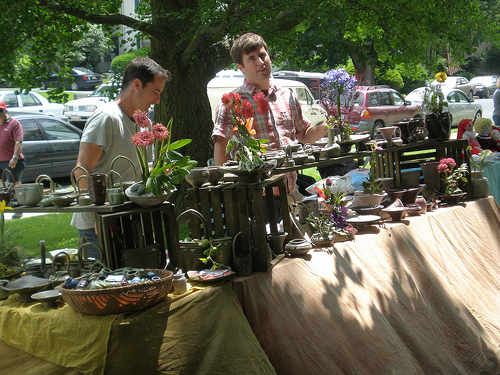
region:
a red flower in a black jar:
[419, 68, 459, 138]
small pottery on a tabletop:
[280, 176, 406, 251]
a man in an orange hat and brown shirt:
[1, 101, 26, 191]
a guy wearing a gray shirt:
[72, 51, 174, 188]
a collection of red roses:
[220, 88, 275, 164]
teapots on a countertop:
[8, 171, 95, 210]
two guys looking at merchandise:
[70, 36, 336, 244]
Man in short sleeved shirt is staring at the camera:
[203, 30, 336, 157]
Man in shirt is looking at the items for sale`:
[63, 50, 183, 253]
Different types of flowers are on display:
[115, 60, 415, 196]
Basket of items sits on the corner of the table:
[50, 257, 187, 320]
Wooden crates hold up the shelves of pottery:
[77, 141, 497, 298]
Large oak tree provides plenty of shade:
[18, 9, 493, 189]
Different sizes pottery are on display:
[10, 125, 465, 256]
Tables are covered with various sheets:
[8, 198, 498, 365]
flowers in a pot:
[122, 105, 182, 192]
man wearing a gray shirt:
[76, 101, 141, 206]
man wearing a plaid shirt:
[219, 80, 298, 173]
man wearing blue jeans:
[72, 223, 100, 261]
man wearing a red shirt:
[0, 117, 26, 161]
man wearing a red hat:
[1, 98, 7, 110]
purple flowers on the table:
[320, 176, 360, 247]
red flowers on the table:
[212, 85, 279, 144]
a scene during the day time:
[5, 0, 497, 374]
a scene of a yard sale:
[3, 5, 489, 372]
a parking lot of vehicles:
[7, 20, 490, 200]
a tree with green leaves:
[0, 0, 497, 202]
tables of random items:
[0, 59, 499, 371]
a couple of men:
[65, 28, 340, 271]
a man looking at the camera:
[187, 24, 352, 251]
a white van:
[181, 70, 346, 160]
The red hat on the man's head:
[0, 99, 7, 113]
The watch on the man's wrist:
[10, 152, 20, 164]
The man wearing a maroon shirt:
[0, 100, 24, 200]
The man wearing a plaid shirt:
[207, 27, 332, 212]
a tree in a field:
[12, 5, 307, 179]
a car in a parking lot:
[9, 100, 98, 177]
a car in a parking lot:
[2, 80, 62, 124]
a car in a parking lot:
[62, 96, 112, 123]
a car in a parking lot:
[341, 83, 418, 121]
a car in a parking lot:
[405, 90, 483, 128]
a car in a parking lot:
[416, 73, 469, 98]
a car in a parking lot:
[465, 72, 495, 99]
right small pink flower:
[130, 125, 152, 150]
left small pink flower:
[154, 125, 169, 140]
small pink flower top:
[131, 109, 155, 127]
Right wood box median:
[97, 210, 179, 265]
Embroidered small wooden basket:
[66, 271, 167, 313]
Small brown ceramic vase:
[287, 236, 312, 256]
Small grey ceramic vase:
[10, 182, 45, 202]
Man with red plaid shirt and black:
[230, 30, 314, 152]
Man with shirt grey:
[85, 62, 168, 172]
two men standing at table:
[70, 32, 359, 372]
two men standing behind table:
[70, 31, 352, 366]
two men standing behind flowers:
[69, 33, 356, 192]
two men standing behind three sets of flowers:
[73, 29, 379, 196]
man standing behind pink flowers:
[71, 48, 198, 222]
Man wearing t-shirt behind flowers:
[77, 51, 184, 216]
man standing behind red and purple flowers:
[211, 32, 360, 173]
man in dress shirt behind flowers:
[212, 28, 354, 164]